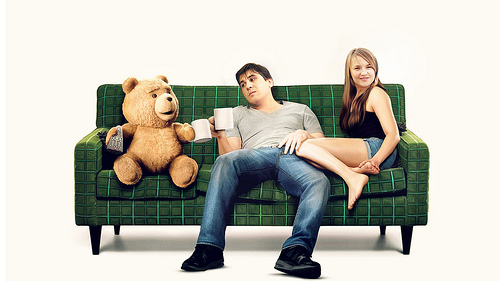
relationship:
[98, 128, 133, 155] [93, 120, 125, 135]
remote control in hands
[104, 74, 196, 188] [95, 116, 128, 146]
bear holding remote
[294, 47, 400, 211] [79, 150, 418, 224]
girl on couch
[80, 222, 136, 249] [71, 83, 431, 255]
legs on couch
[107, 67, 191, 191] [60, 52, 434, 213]
bear on couch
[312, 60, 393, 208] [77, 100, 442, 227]
girl sitting couch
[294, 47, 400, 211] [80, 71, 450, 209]
girl on couch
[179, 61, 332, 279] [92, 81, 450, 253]
boy on sofa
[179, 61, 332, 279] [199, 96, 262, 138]
boy with cup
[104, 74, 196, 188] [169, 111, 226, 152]
bear with cup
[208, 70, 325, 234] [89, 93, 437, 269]
boy on sofa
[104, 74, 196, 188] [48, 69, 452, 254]
bear on couch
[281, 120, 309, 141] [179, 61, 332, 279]
hand on boy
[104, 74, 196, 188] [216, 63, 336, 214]
bear with man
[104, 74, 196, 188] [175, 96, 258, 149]
bear with mugs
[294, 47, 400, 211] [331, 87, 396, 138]
girl with shirt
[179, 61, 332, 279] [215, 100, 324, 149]
boy with shirt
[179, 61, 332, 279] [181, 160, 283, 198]
boy with pillow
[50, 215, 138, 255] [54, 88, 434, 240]
legs with couch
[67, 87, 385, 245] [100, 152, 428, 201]
couch with pillows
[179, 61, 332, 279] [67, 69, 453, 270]
boy on couch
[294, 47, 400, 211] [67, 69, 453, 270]
girl on couch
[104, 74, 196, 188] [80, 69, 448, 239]
bear on couch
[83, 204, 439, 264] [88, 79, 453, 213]
legs on couch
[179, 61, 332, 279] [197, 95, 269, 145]
boy with cup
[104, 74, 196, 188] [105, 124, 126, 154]
bear with remote control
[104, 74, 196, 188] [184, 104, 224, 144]
bear with cup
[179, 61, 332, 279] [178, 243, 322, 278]
boy with shoes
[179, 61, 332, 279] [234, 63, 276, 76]
boy with hair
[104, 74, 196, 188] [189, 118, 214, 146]
bear holding mug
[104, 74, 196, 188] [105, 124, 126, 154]
bear holding remote control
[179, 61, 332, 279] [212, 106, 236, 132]
boy holding mug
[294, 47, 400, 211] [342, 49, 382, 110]
girl has hair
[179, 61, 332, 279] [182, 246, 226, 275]
boy has shoe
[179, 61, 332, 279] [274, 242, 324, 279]
boy has shoe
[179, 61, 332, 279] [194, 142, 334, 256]
boy wearing jeans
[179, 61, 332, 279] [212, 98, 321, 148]
boy wearing shirt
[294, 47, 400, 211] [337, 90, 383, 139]
girl wearing shirt